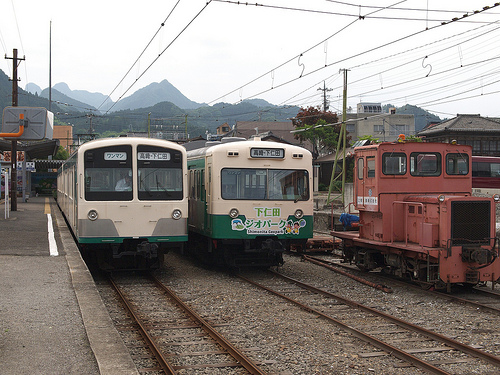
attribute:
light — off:
[171, 209, 181, 221]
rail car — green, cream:
[179, 132, 319, 277]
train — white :
[56, 137, 189, 274]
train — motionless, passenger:
[175, 133, 317, 270]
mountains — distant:
[36, 84, 161, 113]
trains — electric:
[52, 127, 323, 271]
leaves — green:
[315, 128, 331, 143]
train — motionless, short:
[328, 145, 499, 296]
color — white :
[380, 176, 466, 239]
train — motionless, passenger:
[54, 124, 191, 269]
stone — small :
[241, 292, 278, 342]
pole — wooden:
[7, 41, 29, 211]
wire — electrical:
[98, 0, 179, 110]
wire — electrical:
[104, 0, 209, 116]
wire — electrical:
[213, 1, 498, 23]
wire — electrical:
[207, 0, 405, 105]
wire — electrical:
[321, 52, 498, 104]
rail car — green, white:
[51, 132, 192, 272]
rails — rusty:
[269, 288, 481, 368]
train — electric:
[218, 152, 313, 234]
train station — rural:
[1, 99, 481, 360]